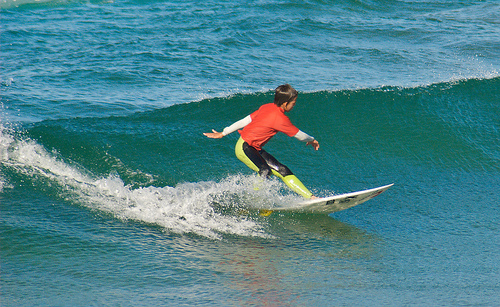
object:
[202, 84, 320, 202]
boy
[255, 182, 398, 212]
surfboard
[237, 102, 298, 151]
shirt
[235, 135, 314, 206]
pants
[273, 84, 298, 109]
hair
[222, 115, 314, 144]
sleeves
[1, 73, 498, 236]
wave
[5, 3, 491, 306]
water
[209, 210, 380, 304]
reflection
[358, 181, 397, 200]
tip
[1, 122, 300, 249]
water